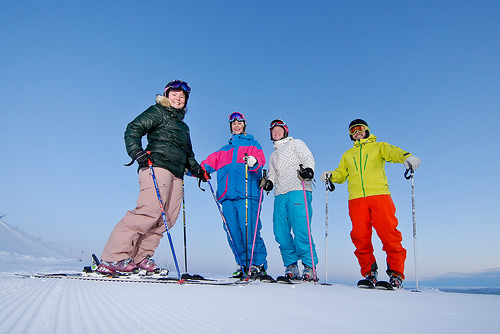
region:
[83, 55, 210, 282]
a women in a green jacket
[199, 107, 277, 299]
a women in a blue ski suit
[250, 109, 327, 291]
a women wearing a sweater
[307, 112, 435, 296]
a women wearing a yellow jacket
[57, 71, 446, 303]
four women skiing on the snow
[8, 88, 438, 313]
four women holding ski sticks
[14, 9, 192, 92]
clear blue skies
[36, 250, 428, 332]
ski boards on the snow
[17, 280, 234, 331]
white snow on the ground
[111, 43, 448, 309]
four women smiling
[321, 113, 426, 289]
person in a yellow jacket and orange pants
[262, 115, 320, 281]
person in a white jacket and blue pants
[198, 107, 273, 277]
person in a blue and pink ski outfit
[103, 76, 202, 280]
person in a dark jacket and tan pants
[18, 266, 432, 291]
four sets of skies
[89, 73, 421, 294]
group of four friends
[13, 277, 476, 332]
clean white snow on the ground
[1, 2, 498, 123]
clear blue sky in top of picture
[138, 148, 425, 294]
four sets of ski poles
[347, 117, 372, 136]
man wearing yellow and orange ski goggles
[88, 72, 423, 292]
Four skiers posing for the camera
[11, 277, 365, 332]
Snow on ground has ski track on it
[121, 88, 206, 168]
Black coat with fur trim by collar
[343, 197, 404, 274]
Bright orange ski pants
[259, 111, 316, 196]
Woman wearing only a turtleneck in winter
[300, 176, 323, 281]
Pink ski pole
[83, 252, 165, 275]
Pink ski boots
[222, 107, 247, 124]
Blue ski goggles on woman's forehead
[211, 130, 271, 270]
Blue and pink ski suit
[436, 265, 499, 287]
Mountains in the distance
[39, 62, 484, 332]
four people on ski slope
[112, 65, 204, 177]
lady wearing black snow coat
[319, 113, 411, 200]
person wearing yellow snow coat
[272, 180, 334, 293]
bright blue snow pants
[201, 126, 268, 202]
womans blue snow jacket with pink stripe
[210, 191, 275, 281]
ladies bright blue snow pants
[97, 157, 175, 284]
womans gray snow pants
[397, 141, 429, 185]
white snow gloves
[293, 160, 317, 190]
black snow gloves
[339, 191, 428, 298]
bright orange snow pants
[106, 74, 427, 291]
Four skiers posing together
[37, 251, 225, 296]
Skis on the snow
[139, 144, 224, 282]
Two blue ski poles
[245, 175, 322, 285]
Two pink ski poles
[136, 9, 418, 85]
A blue sky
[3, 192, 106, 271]
A snowy slope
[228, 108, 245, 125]
Blue and pink ski goggles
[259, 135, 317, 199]
A woman wearing a turtleneck shirt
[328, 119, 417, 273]
A skier wearing a yellow jacket and red pants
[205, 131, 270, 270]
A matching blue and pink ski outfit